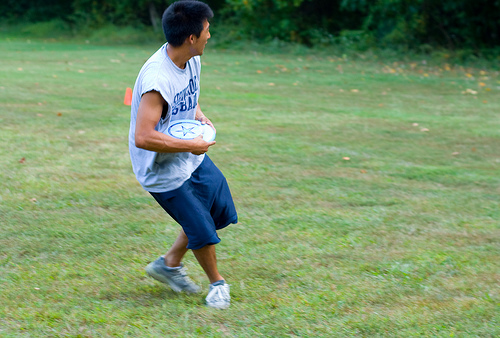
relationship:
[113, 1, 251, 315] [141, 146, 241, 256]
guy wearing shorts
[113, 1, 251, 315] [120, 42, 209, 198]
guy wearing shirt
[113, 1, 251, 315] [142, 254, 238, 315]
guy wearing shoes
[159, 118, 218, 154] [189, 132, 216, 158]
frisbee in hand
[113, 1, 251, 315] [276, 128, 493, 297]
guy in grass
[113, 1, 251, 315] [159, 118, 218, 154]
guy holding frisbee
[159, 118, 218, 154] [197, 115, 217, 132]
frisbee in hand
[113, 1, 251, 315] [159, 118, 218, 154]
guy playing frisbee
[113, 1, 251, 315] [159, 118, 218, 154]
guy catches frisbee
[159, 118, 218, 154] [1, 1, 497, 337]
frisbee in park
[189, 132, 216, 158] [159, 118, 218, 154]
hand on frisbee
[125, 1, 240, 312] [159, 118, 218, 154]
guy has frisbee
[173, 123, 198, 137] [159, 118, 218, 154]
star on frisbee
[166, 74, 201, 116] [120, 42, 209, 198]
writing on shirt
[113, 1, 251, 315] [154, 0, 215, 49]
guy has hair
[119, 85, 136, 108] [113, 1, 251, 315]
flag behind guy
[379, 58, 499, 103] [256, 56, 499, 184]
leaves on ground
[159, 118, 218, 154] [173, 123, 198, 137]
frisbee has star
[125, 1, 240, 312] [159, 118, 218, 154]
guy playing frisbee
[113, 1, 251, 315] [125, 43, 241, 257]
guy in clothes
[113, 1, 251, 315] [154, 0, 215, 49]
guy with hair